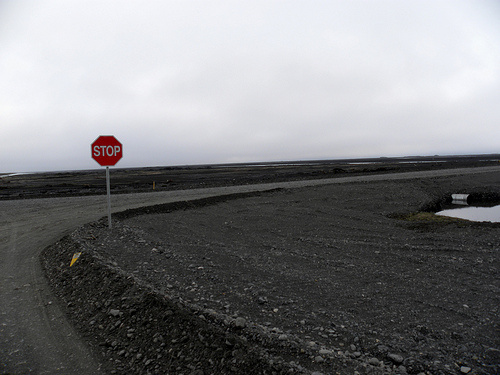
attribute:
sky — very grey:
[120, 34, 437, 144]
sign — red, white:
[89, 130, 124, 169]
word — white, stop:
[93, 140, 121, 158]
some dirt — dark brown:
[189, 220, 342, 317]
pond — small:
[424, 189, 484, 229]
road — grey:
[9, 166, 460, 361]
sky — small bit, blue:
[2, 7, 15, 24]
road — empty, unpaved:
[1, 164, 484, 371]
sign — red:
[90, 133, 123, 167]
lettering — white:
[92, 143, 121, 157]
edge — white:
[89, 133, 124, 167]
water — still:
[433, 205, 483, 222]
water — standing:
[432, 203, 483, 221]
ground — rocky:
[38, 170, 482, 372]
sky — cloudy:
[1, 2, 484, 174]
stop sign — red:
[90, 134, 123, 166]